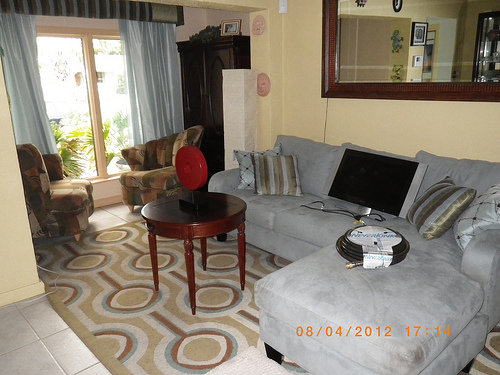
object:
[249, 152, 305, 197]
pillows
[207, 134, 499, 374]
sectional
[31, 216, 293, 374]
area rug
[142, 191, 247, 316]
table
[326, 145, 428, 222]
television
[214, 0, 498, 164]
walls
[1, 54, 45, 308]
walls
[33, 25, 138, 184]
frame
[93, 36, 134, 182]
window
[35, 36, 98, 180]
window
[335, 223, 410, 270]
cable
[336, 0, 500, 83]
mirror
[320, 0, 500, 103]
frame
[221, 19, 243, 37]
framed picture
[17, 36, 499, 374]
furniture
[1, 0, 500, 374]
living room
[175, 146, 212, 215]
statue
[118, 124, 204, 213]
chair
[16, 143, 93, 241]
chair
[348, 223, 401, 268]
packaging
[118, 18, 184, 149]
curtain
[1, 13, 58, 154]
curtain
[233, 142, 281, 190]
pillow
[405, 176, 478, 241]
pillow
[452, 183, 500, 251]
pillow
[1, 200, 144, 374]
tile floor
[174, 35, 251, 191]
cabinet